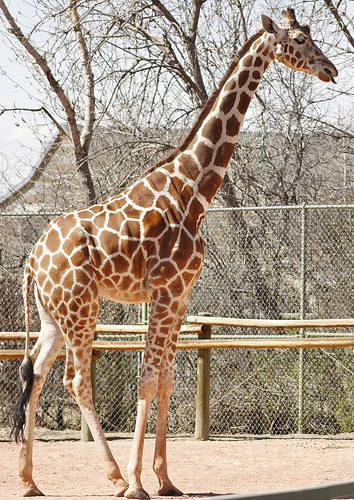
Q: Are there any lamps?
A: No, there are no lamps.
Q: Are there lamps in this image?
A: No, there are no lamps.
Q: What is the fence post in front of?
A: The fence post is in front of the fence.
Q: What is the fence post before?
A: The fence post is in front of the fence.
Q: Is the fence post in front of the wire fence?
A: Yes, the fence post is in front of the fence.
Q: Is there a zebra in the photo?
A: No, there are no zebras.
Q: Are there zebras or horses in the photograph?
A: No, there are no zebras or horses.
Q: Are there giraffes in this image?
A: Yes, there is a giraffe.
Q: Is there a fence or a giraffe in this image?
A: Yes, there is a giraffe.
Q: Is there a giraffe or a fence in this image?
A: Yes, there is a giraffe.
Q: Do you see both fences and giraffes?
A: Yes, there are both a giraffe and a fence.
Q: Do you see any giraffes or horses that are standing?
A: Yes, the giraffe is standing.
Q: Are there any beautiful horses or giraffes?
A: Yes, there is a beautiful giraffe.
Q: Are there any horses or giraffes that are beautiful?
A: Yes, the giraffe is beautiful.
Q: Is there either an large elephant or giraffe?
A: Yes, there is a large giraffe.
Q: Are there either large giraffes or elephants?
A: Yes, there is a large giraffe.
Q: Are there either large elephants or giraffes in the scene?
A: Yes, there is a large giraffe.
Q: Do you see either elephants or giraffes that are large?
A: Yes, the giraffe is large.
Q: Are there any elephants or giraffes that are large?
A: Yes, the giraffe is large.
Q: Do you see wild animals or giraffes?
A: Yes, there is a wild giraffe.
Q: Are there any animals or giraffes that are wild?
A: Yes, the giraffe is wild.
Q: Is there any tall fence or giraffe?
A: Yes, there is a tall giraffe.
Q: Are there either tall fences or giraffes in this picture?
A: Yes, there is a tall giraffe.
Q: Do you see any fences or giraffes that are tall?
A: Yes, the giraffe is tall.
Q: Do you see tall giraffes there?
A: Yes, there is a tall giraffe.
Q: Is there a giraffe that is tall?
A: Yes, there is a giraffe that is tall.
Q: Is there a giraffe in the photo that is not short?
A: Yes, there is a tall giraffe.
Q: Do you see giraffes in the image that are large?
A: Yes, there is a large giraffe.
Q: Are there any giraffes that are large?
A: Yes, there is a giraffe that is large.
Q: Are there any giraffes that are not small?
A: Yes, there is a large giraffe.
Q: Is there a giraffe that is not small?
A: Yes, there is a large giraffe.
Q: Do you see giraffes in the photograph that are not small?
A: Yes, there is a large giraffe.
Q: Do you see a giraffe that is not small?
A: Yes, there is a large giraffe.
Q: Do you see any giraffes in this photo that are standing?
A: Yes, there is a giraffe that is standing.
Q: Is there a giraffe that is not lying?
A: Yes, there is a giraffe that is standing.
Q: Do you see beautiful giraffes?
A: Yes, there is a beautiful giraffe.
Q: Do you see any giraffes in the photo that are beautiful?
A: Yes, there is a giraffe that is beautiful.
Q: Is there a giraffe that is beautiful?
A: Yes, there is a giraffe that is beautiful.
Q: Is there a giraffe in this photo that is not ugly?
A: Yes, there is an beautiful giraffe.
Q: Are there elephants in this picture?
A: No, there are no elephants.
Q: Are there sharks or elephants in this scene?
A: No, there are no elephants or sharks.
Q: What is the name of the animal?
A: The animal is a giraffe.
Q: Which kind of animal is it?
A: The animal is a giraffe.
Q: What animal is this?
A: This is a giraffe.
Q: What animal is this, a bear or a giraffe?
A: This is a giraffe.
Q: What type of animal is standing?
A: The animal is a giraffe.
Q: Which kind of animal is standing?
A: The animal is a giraffe.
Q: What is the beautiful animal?
A: The animal is a giraffe.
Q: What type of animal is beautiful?
A: The animal is a giraffe.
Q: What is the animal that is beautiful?
A: The animal is a giraffe.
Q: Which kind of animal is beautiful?
A: The animal is a giraffe.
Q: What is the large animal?
A: The animal is a giraffe.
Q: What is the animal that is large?
A: The animal is a giraffe.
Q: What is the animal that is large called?
A: The animal is a giraffe.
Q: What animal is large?
A: The animal is a giraffe.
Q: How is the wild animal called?
A: The animal is a giraffe.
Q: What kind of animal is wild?
A: The animal is a giraffe.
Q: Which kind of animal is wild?
A: The animal is a giraffe.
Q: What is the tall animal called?
A: The animal is a giraffe.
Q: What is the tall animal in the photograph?
A: The animal is a giraffe.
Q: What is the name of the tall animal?
A: The animal is a giraffe.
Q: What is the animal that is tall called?
A: The animal is a giraffe.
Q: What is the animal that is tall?
A: The animal is a giraffe.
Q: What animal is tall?
A: The animal is a giraffe.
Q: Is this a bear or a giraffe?
A: This is a giraffe.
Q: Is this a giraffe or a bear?
A: This is a giraffe.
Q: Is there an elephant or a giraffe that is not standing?
A: No, there is a giraffe but it is standing.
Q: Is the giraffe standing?
A: Yes, the giraffe is standing.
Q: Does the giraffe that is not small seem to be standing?
A: Yes, the giraffe is standing.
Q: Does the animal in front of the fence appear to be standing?
A: Yes, the giraffe is standing.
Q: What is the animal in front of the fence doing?
A: The giraffe is standing.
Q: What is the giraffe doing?
A: The giraffe is standing.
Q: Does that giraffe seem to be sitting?
A: No, the giraffe is standing.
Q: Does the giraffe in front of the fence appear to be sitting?
A: No, the giraffe is standing.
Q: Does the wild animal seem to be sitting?
A: No, the giraffe is standing.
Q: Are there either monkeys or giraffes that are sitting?
A: No, there is a giraffe but it is standing.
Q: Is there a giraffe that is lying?
A: No, there is a giraffe but it is standing.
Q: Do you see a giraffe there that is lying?
A: No, there is a giraffe but it is standing.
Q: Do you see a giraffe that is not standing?
A: No, there is a giraffe but it is standing.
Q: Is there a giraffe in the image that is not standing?
A: No, there is a giraffe but it is standing.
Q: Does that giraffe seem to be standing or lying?
A: The giraffe is standing.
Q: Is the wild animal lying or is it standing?
A: The giraffe is standing.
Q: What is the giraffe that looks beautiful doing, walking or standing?
A: The giraffe is standing.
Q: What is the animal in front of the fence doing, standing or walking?
A: The giraffe is standing.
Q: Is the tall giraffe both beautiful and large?
A: Yes, the giraffe is beautiful and large.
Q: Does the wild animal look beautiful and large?
A: Yes, the giraffe is beautiful and large.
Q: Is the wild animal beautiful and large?
A: Yes, the giraffe is beautiful and large.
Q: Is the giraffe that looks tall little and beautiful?
A: No, the giraffe is beautiful but large.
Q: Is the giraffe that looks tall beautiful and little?
A: No, the giraffe is beautiful but large.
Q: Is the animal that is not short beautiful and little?
A: No, the giraffe is beautiful but large.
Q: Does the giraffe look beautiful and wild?
A: Yes, the giraffe is beautiful and wild.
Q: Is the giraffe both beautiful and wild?
A: Yes, the giraffe is beautiful and wild.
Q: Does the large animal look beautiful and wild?
A: Yes, the giraffe is beautiful and wild.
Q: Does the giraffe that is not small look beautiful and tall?
A: Yes, the giraffe is beautiful and tall.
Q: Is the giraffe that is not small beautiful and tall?
A: Yes, the giraffe is beautiful and tall.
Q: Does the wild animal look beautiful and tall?
A: Yes, the giraffe is beautiful and tall.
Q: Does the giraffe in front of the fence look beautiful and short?
A: No, the giraffe is beautiful but tall.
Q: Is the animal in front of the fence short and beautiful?
A: No, the giraffe is beautiful but tall.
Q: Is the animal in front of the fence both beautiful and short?
A: No, the giraffe is beautiful but tall.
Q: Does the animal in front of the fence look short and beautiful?
A: No, the giraffe is beautiful but tall.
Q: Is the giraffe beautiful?
A: Yes, the giraffe is beautiful.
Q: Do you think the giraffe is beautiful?
A: Yes, the giraffe is beautiful.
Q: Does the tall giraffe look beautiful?
A: Yes, the giraffe is beautiful.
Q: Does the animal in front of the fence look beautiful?
A: Yes, the giraffe is beautiful.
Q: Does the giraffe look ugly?
A: No, the giraffe is beautiful.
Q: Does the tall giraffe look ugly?
A: No, the giraffe is beautiful.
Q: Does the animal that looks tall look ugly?
A: No, the giraffe is beautiful.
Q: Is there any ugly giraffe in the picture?
A: No, there is a giraffe but it is beautiful.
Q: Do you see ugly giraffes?
A: No, there is a giraffe but it is beautiful.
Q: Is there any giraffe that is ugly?
A: No, there is a giraffe but it is beautiful.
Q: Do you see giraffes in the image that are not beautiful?
A: No, there is a giraffe but it is beautiful.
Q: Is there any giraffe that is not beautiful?
A: No, there is a giraffe but it is beautiful.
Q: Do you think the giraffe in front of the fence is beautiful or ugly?
A: The giraffe is beautiful.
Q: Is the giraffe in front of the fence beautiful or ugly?
A: The giraffe is beautiful.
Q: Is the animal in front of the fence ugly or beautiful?
A: The giraffe is beautiful.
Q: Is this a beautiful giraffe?
A: Yes, this is a beautiful giraffe.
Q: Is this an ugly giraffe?
A: No, this is a beautiful giraffe.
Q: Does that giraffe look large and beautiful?
A: Yes, the giraffe is large and beautiful.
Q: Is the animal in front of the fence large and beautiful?
A: Yes, the giraffe is large and beautiful.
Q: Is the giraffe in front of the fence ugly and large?
A: No, the giraffe is large but beautiful.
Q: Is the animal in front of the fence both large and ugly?
A: No, the giraffe is large but beautiful.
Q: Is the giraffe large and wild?
A: Yes, the giraffe is large and wild.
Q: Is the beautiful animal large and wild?
A: Yes, the giraffe is large and wild.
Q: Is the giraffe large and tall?
A: Yes, the giraffe is large and tall.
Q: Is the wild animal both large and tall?
A: Yes, the giraffe is large and tall.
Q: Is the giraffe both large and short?
A: No, the giraffe is large but tall.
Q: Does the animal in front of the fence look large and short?
A: No, the giraffe is large but tall.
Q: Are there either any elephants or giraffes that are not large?
A: No, there is a giraffe but it is large.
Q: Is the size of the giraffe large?
A: Yes, the giraffe is large.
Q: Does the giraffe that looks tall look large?
A: Yes, the giraffe is large.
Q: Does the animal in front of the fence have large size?
A: Yes, the giraffe is large.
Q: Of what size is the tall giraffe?
A: The giraffe is large.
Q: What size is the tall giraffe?
A: The giraffe is large.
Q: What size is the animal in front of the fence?
A: The giraffe is large.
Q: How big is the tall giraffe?
A: The giraffe is large.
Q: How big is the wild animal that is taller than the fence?
A: The giraffe is large.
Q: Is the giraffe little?
A: No, the giraffe is large.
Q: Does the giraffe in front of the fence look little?
A: No, the giraffe is large.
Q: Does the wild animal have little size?
A: No, the giraffe is large.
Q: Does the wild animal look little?
A: No, the giraffe is large.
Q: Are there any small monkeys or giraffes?
A: No, there is a giraffe but it is large.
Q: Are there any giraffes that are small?
A: No, there is a giraffe but it is large.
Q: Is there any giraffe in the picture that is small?
A: No, there is a giraffe but it is large.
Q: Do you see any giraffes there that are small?
A: No, there is a giraffe but it is large.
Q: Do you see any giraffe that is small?
A: No, there is a giraffe but it is large.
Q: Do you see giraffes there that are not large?
A: No, there is a giraffe but it is large.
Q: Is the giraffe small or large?
A: The giraffe is large.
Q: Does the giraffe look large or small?
A: The giraffe is large.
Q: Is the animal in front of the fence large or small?
A: The giraffe is large.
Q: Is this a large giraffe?
A: Yes, this is a large giraffe.